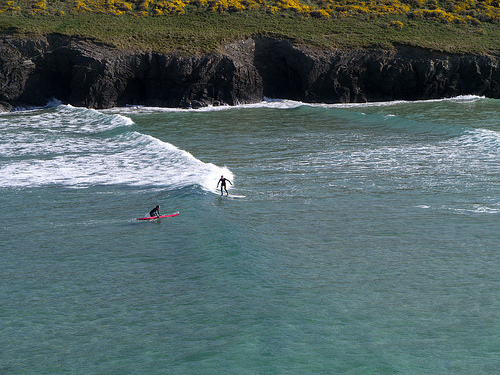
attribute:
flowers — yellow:
[4, 0, 499, 27]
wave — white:
[44, 153, 100, 174]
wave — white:
[4, 106, 234, 204]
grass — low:
[2, 1, 496, 66]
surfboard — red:
[133, 210, 180, 228]